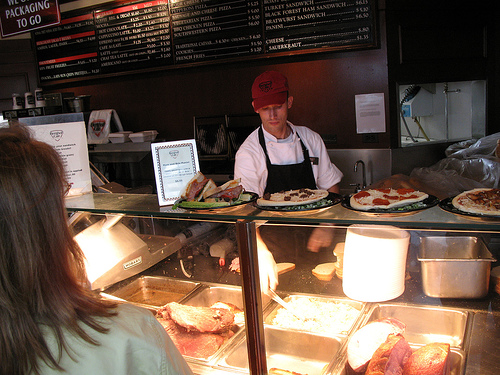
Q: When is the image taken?
A: While serving.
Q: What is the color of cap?
A: Red.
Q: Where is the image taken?
A: Restuarant.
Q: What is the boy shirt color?
A: White.